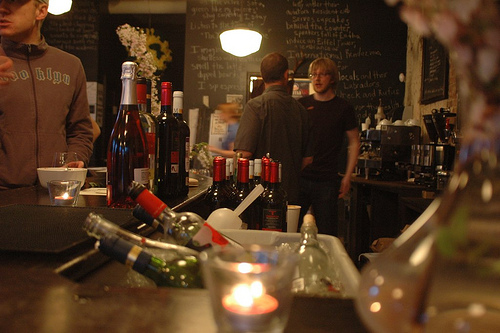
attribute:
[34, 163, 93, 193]
bowl — white 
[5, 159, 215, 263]
table — one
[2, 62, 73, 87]
lettering — colored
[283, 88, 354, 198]
shirt — dark 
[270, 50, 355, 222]
man — one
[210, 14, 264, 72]
light — one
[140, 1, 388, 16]
ceiling — one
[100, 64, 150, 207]
liquid — red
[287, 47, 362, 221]
man — one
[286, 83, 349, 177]
shirt — one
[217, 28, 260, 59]
light — Hanging 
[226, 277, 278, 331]
candle — Orange 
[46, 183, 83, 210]
candle — Orange 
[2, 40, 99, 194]
jacket — one, brown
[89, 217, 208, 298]
bottle — empty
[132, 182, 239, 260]
bottle — empty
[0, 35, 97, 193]
hoodie — brooklyn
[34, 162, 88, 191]
bowl — white, round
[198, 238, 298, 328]
candle — lit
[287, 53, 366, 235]
man — blonde, black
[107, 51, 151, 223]
wine bottle — red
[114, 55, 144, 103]
top — silver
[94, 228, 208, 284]
bottle — one, green, gold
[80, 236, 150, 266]
top — black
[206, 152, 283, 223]
bottles — red, metallic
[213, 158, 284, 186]
tops — red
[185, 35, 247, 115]
chalkboard — black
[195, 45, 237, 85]
writing — white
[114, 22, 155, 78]
flowers — white